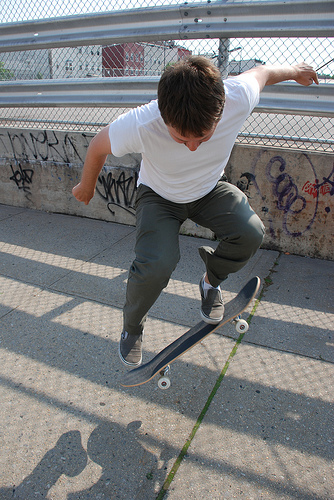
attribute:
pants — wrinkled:
[123, 182, 280, 325]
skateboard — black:
[129, 281, 284, 393]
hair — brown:
[156, 58, 234, 132]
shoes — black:
[105, 272, 256, 363]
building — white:
[0, 46, 104, 78]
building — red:
[105, 43, 144, 75]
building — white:
[140, 45, 174, 75]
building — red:
[178, 44, 200, 61]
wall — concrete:
[0, 107, 333, 229]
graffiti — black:
[6, 133, 82, 165]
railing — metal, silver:
[2, 17, 333, 111]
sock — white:
[199, 269, 220, 294]